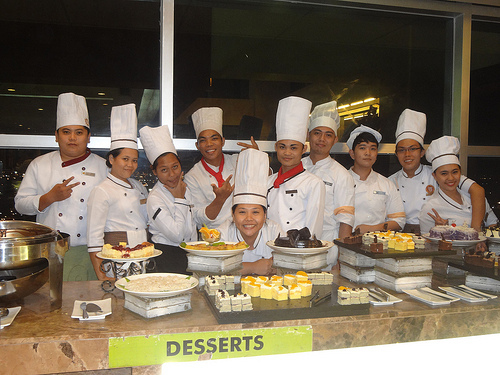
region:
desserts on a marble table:
[338, 287, 370, 304]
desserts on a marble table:
[238, 276, 309, 297]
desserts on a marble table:
[96, 244, 161, 263]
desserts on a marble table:
[183, 237, 248, 257]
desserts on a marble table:
[275, 232, 326, 251]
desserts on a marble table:
[343, 234, 423, 256]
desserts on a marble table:
[431, 221, 476, 241]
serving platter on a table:
[72, 298, 112, 323]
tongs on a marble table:
[308, 290, 328, 305]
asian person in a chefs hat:
[233, 154, 268, 241]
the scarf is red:
[198, 156, 244, 207]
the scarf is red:
[194, 162, 243, 189]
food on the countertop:
[72, 209, 490, 338]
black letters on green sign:
[106, 326, 316, 370]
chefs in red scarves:
[190, 90, 317, 192]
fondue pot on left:
[0, 215, 75, 335]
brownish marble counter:
[0, 243, 497, 373]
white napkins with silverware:
[362, 275, 499, 310]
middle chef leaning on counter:
[208, 151, 286, 263]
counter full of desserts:
[2, 220, 499, 374]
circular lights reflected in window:
[1, 82, 144, 212]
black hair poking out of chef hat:
[346, 122, 385, 174]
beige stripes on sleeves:
[332, 200, 411, 225]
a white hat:
[234, 150, 270, 200]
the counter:
[13, 310, 53, 345]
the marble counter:
[169, 313, 204, 327]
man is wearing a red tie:
[206, 166, 225, 176]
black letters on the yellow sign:
[162, 334, 274, 356]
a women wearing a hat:
[107, 102, 138, 181]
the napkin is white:
[99, 295, 114, 307]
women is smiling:
[232, 197, 265, 234]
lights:
[345, 93, 388, 118]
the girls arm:
[466, 181, 480, 209]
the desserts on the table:
[95, 222, 499, 311]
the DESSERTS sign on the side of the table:
[107, 325, 311, 367]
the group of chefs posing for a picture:
[14, 91, 496, 278]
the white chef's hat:
[231, 147, 269, 207]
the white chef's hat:
[55, 91, 89, 129]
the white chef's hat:
[425, 135, 460, 171]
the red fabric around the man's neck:
[272, 160, 303, 187]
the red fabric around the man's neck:
[200, 153, 225, 188]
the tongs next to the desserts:
[307, 288, 332, 306]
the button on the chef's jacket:
[79, 196, 85, 203]